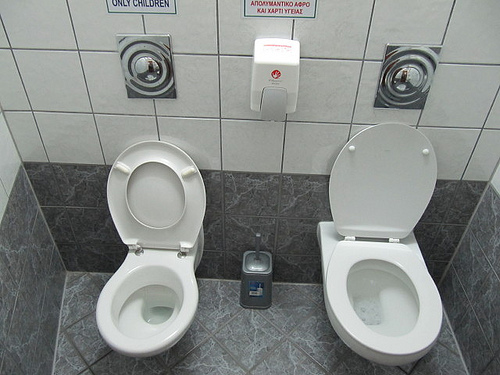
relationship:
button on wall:
[391, 64, 423, 94] [19, 16, 121, 134]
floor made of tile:
[50, 270, 465, 374] [212, 305, 285, 368]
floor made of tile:
[50, 270, 465, 374] [287, 306, 351, 371]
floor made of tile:
[50, 270, 465, 374] [413, 341, 467, 372]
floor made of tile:
[50, 270, 465, 374] [65, 310, 117, 363]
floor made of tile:
[50, 270, 465, 374] [62, 270, 85, 282]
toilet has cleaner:
[90, 132, 214, 363] [230, 220, 281, 317]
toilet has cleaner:
[314, 108, 456, 370] [230, 220, 281, 317]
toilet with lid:
[316, 122, 442, 367] [327, 120, 438, 244]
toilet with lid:
[94, 140, 205, 359] [102, 140, 206, 252]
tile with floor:
[0, 0, 500, 375] [212, 297, 289, 358]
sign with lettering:
[240, 2, 322, 20] [248, 2, 308, 14]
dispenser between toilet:
[248, 37, 304, 120] [316, 122, 442, 367]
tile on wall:
[0, 0, 500, 375] [8, 0, 497, 184]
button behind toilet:
[388, 66, 422, 95] [316, 122, 442, 367]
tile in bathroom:
[151, 50, 222, 121] [11, 75, 498, 373]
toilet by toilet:
[316, 122, 442, 367] [90, 132, 214, 363]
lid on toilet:
[327, 122, 443, 237] [321, 116, 457, 362]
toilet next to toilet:
[316, 122, 442, 367] [90, 132, 214, 363]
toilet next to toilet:
[316, 122, 442, 367] [94, 140, 205, 359]